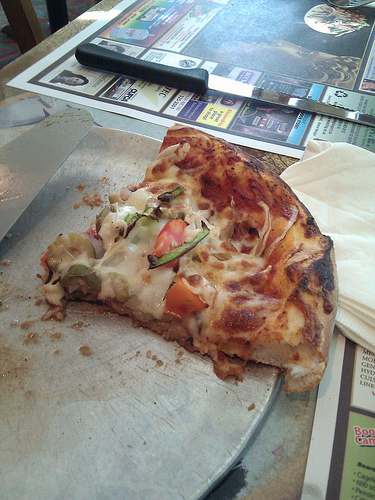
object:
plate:
[0, 124, 280, 500]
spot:
[292, 250, 335, 294]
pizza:
[35, 124, 339, 395]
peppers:
[157, 186, 183, 203]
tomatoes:
[151, 217, 190, 268]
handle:
[75, 42, 208, 95]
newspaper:
[5, 0, 375, 160]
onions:
[45, 233, 94, 268]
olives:
[59, 265, 100, 300]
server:
[0, 402, 126, 500]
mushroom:
[63, 263, 102, 301]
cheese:
[68, 169, 253, 324]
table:
[0, 0, 373, 500]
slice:
[37, 122, 337, 393]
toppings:
[49, 188, 212, 321]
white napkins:
[278, 138, 375, 357]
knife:
[74, 42, 375, 130]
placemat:
[6, 0, 374, 159]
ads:
[100, 48, 203, 116]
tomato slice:
[163, 280, 208, 320]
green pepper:
[146, 219, 210, 270]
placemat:
[299, 329, 374, 500]